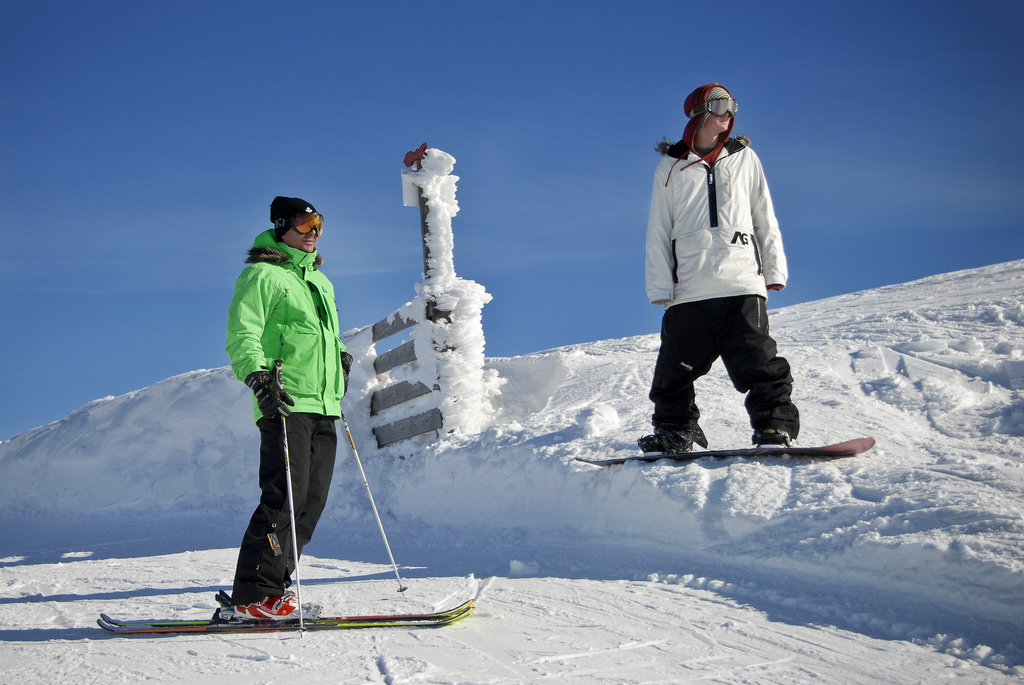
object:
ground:
[0, 260, 1024, 684]